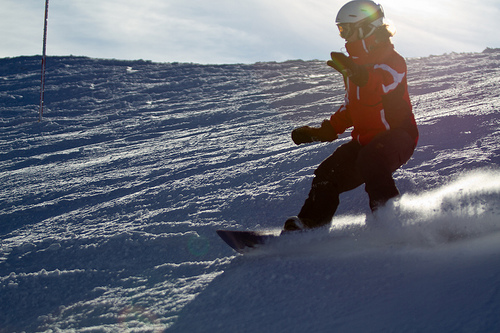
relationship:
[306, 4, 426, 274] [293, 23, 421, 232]
snowboarder in uniform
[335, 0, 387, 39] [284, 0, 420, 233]
helmet on snowboarder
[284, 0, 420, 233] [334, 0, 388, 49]
snowboarder has head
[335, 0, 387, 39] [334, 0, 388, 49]
helmet on head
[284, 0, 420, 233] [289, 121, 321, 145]
snowboarder has glove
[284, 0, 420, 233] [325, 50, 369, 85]
snowboarder has glove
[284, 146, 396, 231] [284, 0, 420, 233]
pants on snowboarder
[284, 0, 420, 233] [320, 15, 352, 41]
snowboarder has lenses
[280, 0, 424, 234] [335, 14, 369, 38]
person wearing goggles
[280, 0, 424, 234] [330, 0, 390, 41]
person wearing helmet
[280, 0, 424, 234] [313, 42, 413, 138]
person wearing jacket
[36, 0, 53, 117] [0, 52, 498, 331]
pole in ground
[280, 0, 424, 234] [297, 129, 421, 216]
person wearing pants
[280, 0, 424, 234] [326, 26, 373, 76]
person holding hand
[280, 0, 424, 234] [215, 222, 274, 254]
person on snowboard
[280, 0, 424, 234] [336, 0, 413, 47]
person with helmet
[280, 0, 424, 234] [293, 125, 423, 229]
person with pants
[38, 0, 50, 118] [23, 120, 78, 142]
pole in snow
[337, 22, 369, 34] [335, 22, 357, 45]
goggles on face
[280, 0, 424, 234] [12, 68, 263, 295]
person going down hill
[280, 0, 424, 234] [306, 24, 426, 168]
person wearing jacket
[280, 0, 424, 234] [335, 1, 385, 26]
person wearing helmet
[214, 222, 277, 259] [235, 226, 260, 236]
snowboard seen part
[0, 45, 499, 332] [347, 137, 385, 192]
snow on ground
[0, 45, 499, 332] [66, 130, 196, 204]
snow on track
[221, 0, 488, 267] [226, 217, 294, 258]
person on snow board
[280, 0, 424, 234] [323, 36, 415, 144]
person wearing jacket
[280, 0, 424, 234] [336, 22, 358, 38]
person wearing goggles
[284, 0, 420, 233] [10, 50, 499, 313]
snowboarder on snowy slope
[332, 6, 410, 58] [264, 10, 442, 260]
helmet on snowboarder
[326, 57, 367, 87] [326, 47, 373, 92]
hand in glove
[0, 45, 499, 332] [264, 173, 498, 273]
snow flying into air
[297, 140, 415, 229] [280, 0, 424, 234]
pants on person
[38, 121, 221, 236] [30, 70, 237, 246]
lines in snow surface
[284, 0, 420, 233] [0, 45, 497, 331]
snowboarder on snow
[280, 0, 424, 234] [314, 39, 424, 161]
person wearing jacket